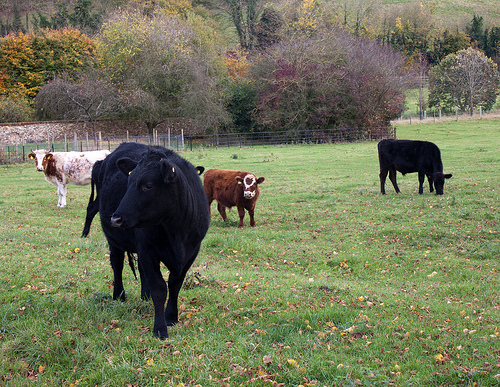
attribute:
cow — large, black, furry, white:
[81, 140, 211, 339]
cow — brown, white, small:
[200, 169, 263, 227]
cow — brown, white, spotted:
[26, 146, 110, 209]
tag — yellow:
[30, 154, 34, 160]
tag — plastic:
[235, 178, 241, 185]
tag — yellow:
[127, 165, 132, 175]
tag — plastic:
[170, 167, 177, 175]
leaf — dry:
[285, 355, 301, 367]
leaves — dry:
[2, 186, 497, 386]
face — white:
[29, 152, 51, 169]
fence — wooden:
[3, 125, 187, 162]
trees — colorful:
[0, 14, 406, 142]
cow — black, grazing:
[373, 136, 454, 193]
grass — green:
[3, 122, 500, 384]